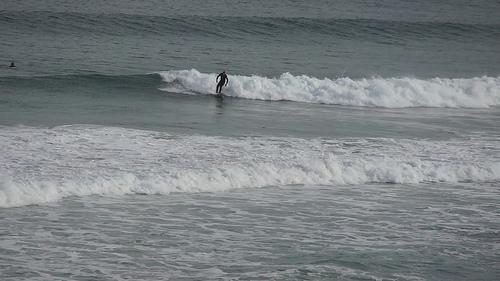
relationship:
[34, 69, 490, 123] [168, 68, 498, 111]
wave has foam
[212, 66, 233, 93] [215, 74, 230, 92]
man wearing wetsuit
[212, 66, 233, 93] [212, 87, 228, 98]
man on surfboard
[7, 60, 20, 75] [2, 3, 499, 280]
man in water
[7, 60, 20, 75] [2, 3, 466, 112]
man in background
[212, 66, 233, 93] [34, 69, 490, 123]
man on wave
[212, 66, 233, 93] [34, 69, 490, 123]
man standing on wave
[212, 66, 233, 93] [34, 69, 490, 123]
man riding wave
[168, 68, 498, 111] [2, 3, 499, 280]
foam in water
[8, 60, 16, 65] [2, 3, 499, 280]
head above water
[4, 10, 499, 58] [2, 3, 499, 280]
reflection on water